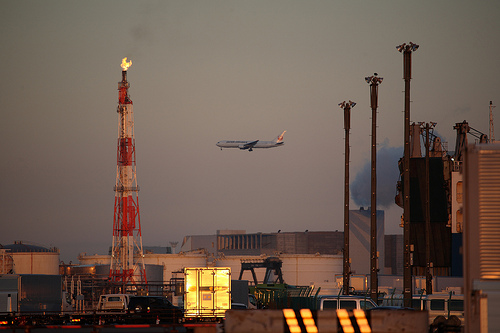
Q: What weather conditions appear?
A: It is foggy.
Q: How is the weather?
A: It is foggy.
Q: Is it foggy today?
A: Yes, it is foggy.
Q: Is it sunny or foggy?
A: It is foggy.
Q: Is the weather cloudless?
A: No, it is foggy.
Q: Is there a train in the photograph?
A: No, there are no trains.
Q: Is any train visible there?
A: No, there are no trains.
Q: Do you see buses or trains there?
A: No, there are no trains or buses.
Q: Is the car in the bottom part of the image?
A: Yes, the car is in the bottom of the image.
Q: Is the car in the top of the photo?
A: No, the car is in the bottom of the image.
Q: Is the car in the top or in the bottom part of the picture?
A: The car is in the bottom of the image.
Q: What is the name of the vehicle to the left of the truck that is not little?
A: The vehicle is a car.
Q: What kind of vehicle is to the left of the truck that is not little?
A: The vehicle is a car.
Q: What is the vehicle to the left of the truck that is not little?
A: The vehicle is a car.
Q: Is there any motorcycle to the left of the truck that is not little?
A: No, there is a car to the left of the truck.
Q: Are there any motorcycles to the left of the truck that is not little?
A: No, there is a car to the left of the truck.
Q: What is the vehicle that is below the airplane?
A: The vehicle is a car.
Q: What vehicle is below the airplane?
A: The vehicle is a car.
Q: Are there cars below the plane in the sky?
A: Yes, there is a car below the plane.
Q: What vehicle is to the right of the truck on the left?
A: The vehicle is a car.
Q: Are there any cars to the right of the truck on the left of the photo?
A: Yes, there is a car to the right of the truck.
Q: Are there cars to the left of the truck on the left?
A: No, the car is to the right of the truck.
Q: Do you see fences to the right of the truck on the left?
A: No, there is a car to the right of the truck.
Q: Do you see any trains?
A: No, there are no trains.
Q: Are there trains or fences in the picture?
A: No, there are no trains or fences.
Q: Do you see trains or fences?
A: No, there are no trains or fences.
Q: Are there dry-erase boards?
A: No, there are no dry-erase boards.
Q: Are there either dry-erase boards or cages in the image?
A: No, there are no dry-erase boards or cages.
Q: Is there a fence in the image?
A: No, there are no fences.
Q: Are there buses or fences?
A: No, there are no fences or buses.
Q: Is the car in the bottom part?
A: Yes, the car is in the bottom of the image.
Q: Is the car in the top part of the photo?
A: No, the car is in the bottom of the image.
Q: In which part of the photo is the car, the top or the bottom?
A: The car is in the bottom of the image.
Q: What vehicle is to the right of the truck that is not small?
A: The vehicle is a car.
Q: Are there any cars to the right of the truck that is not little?
A: Yes, there is a car to the right of the truck.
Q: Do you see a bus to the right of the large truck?
A: No, there is a car to the right of the truck.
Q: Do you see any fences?
A: No, there are no fences.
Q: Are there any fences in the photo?
A: No, there are no fences.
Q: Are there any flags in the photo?
A: No, there are no flags.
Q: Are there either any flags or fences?
A: No, there are no flags or fences.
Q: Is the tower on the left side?
A: Yes, the tower is on the left of the image.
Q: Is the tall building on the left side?
A: Yes, the tower is on the left of the image.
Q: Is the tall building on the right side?
A: No, the tower is on the left of the image.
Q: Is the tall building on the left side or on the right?
A: The tower is on the left of the image.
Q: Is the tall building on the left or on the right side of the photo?
A: The tower is on the left of the image.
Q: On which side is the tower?
A: The tower is on the left of the image.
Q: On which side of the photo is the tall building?
A: The tower is on the left of the image.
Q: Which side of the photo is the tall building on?
A: The tower is on the left of the image.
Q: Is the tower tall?
A: Yes, the tower is tall.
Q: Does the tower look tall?
A: Yes, the tower is tall.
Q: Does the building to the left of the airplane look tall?
A: Yes, the tower is tall.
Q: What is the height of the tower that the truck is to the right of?
A: The tower is tall.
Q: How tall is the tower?
A: The tower is tall.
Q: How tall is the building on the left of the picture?
A: The tower is tall.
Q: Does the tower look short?
A: No, the tower is tall.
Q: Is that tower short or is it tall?
A: The tower is tall.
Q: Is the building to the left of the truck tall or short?
A: The tower is tall.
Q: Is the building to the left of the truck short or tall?
A: The tower is tall.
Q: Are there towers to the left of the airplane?
A: Yes, there is a tower to the left of the airplane.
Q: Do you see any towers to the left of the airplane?
A: Yes, there is a tower to the left of the airplane.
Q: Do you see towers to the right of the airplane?
A: No, the tower is to the left of the airplane.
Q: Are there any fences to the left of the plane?
A: No, there is a tower to the left of the plane.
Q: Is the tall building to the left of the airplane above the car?
A: Yes, the tower is to the left of the plane.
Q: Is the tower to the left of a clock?
A: No, the tower is to the left of the plane.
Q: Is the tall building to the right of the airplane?
A: No, the tower is to the left of the airplane.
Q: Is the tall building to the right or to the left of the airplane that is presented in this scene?
A: The tower is to the left of the airplane.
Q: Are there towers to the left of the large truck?
A: Yes, there is a tower to the left of the truck.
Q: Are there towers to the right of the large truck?
A: No, the tower is to the left of the truck.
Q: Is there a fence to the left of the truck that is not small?
A: No, there is a tower to the left of the truck.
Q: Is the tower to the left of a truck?
A: Yes, the tower is to the left of a truck.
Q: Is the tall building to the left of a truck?
A: Yes, the tower is to the left of a truck.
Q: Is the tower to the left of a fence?
A: No, the tower is to the left of a truck.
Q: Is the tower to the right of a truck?
A: No, the tower is to the left of a truck.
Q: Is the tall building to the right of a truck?
A: No, the tower is to the left of a truck.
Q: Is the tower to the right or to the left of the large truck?
A: The tower is to the left of the truck.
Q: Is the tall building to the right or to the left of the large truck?
A: The tower is to the left of the truck.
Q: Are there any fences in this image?
A: No, there are no fences.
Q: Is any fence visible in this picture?
A: No, there are no fences.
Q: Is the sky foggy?
A: Yes, the sky is foggy.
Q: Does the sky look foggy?
A: Yes, the sky is foggy.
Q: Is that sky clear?
A: No, the sky is foggy.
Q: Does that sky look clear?
A: No, the sky is foggy.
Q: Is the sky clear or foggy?
A: The sky is foggy.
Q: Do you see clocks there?
A: No, there are no clocks.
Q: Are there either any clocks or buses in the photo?
A: No, there are no clocks or buses.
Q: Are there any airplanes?
A: Yes, there is an airplane.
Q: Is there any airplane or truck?
A: Yes, there is an airplane.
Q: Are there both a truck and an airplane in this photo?
A: Yes, there are both an airplane and a truck.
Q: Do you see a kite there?
A: No, there are no kites.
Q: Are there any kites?
A: No, there are no kites.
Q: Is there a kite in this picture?
A: No, there are no kites.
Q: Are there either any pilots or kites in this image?
A: No, there are no kites or pilots.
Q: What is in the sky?
A: The plane is in the sky.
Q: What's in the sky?
A: The plane is in the sky.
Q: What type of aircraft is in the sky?
A: The aircraft is an airplane.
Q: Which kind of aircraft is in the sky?
A: The aircraft is an airplane.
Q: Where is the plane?
A: The plane is in the sky.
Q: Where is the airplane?
A: The plane is in the sky.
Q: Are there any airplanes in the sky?
A: Yes, there is an airplane in the sky.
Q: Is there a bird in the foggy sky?
A: No, there is an airplane in the sky.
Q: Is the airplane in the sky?
A: Yes, the airplane is in the sky.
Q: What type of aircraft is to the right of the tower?
A: The aircraft is an airplane.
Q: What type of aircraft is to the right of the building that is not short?
A: The aircraft is an airplane.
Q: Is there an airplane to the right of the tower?
A: Yes, there is an airplane to the right of the tower.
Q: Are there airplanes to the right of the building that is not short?
A: Yes, there is an airplane to the right of the tower.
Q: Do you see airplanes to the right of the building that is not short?
A: Yes, there is an airplane to the right of the tower.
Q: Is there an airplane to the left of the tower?
A: No, the airplane is to the right of the tower.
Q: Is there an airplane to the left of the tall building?
A: No, the airplane is to the right of the tower.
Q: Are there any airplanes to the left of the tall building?
A: No, the airplane is to the right of the tower.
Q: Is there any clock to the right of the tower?
A: No, there is an airplane to the right of the tower.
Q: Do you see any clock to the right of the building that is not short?
A: No, there is an airplane to the right of the tower.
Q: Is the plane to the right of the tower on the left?
A: Yes, the plane is to the right of the tower.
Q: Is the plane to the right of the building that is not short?
A: Yes, the plane is to the right of the tower.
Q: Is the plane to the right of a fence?
A: No, the plane is to the right of the tower.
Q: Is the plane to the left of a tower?
A: No, the plane is to the right of a tower.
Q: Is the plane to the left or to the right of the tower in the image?
A: The plane is to the right of the tower.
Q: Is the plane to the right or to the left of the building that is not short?
A: The plane is to the right of the tower.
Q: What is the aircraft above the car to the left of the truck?
A: The aircraft is an airplane.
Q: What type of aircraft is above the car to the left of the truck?
A: The aircraft is an airplane.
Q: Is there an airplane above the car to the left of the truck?
A: Yes, there is an airplane above the car.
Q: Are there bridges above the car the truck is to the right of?
A: No, there is an airplane above the car.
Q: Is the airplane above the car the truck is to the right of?
A: Yes, the airplane is above the car.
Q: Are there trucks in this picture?
A: Yes, there is a truck.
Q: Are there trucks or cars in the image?
A: Yes, there is a truck.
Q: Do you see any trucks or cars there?
A: Yes, there is a truck.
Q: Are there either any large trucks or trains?
A: Yes, there is a large truck.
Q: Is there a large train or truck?
A: Yes, there is a large truck.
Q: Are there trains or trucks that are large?
A: Yes, the truck is large.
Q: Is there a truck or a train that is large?
A: Yes, the truck is large.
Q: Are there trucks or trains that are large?
A: Yes, the truck is large.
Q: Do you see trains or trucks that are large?
A: Yes, the truck is large.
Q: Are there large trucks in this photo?
A: Yes, there is a large truck.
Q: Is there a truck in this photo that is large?
A: Yes, there is a truck that is large.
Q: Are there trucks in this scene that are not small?
A: Yes, there is a large truck.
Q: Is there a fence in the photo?
A: No, there are no fences.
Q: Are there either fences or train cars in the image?
A: No, there are no fences or train cars.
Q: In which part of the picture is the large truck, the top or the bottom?
A: The truck is in the bottom of the image.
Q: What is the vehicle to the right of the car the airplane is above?
A: The vehicle is a truck.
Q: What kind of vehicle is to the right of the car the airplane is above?
A: The vehicle is a truck.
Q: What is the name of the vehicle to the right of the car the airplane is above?
A: The vehicle is a truck.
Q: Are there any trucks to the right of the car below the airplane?
A: Yes, there is a truck to the right of the car.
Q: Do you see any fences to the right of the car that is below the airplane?
A: No, there is a truck to the right of the car.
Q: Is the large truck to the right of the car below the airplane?
A: Yes, the truck is to the right of the car.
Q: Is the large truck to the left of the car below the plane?
A: No, the truck is to the right of the car.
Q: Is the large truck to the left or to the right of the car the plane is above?
A: The truck is to the right of the car.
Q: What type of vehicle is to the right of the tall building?
A: The vehicle is a truck.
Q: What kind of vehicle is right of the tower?
A: The vehicle is a truck.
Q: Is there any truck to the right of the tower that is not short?
A: Yes, there is a truck to the right of the tower.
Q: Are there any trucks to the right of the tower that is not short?
A: Yes, there is a truck to the right of the tower.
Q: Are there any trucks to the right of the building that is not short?
A: Yes, there is a truck to the right of the tower.